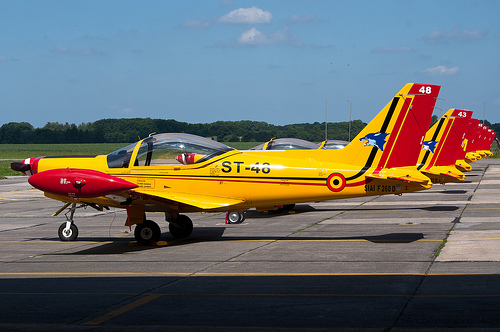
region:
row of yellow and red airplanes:
[12, 60, 496, 229]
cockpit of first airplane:
[107, 130, 216, 167]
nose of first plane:
[5, 148, 35, 181]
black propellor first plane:
[6, 153, 36, 178]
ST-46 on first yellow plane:
[217, 150, 278, 182]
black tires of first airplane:
[51, 214, 196, 250]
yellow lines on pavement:
[3, 228, 485, 327]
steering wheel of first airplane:
[125, 154, 147, 171]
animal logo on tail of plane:
[357, 125, 387, 150]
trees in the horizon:
[5, 113, 493, 141]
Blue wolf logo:
[345, 114, 426, 176]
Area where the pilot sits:
[94, 115, 248, 184]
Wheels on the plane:
[49, 197, 258, 257]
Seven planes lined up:
[11, 69, 496, 272]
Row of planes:
[3, 62, 498, 256]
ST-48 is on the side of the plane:
[209, 140, 292, 183]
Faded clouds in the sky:
[12, 7, 482, 108]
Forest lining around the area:
[2, 87, 481, 151]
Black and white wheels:
[8, 207, 224, 256]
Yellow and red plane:
[10, 42, 491, 264]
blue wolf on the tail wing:
[356, 126, 393, 147]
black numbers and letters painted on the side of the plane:
[223, 154, 273, 180]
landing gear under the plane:
[51, 206, 202, 253]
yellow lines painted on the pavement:
[56, 283, 246, 325]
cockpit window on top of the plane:
[103, 128, 233, 170]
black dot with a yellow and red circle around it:
[324, 168, 348, 194]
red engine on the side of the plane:
[26, 169, 145, 199]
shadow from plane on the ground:
[279, 219, 446, 256]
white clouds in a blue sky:
[180, 3, 325, 59]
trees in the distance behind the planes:
[11, 105, 256, 145]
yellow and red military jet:
[3, 102, 430, 266]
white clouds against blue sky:
[13, 13, 77, 53]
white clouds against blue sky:
[2, 46, 54, 81]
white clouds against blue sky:
[16, 76, 80, 118]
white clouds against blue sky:
[65, 10, 156, 58]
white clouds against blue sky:
[58, 59, 150, 110]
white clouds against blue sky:
[161, 18, 256, 90]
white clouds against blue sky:
[251, 18, 323, 60]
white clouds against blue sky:
[348, 29, 419, 71]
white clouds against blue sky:
[232, 43, 297, 113]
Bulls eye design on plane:
[326, 170, 346, 192]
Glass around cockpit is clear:
[111, 131, 223, 168]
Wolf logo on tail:
[360, 127, 391, 152]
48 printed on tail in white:
[417, 84, 434, 96]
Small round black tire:
[55, 220, 75, 240]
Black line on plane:
[102, 93, 399, 175]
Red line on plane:
[110, 93, 416, 188]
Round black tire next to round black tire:
[135, 215, 160, 245]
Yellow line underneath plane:
[0, 236, 499, 244]